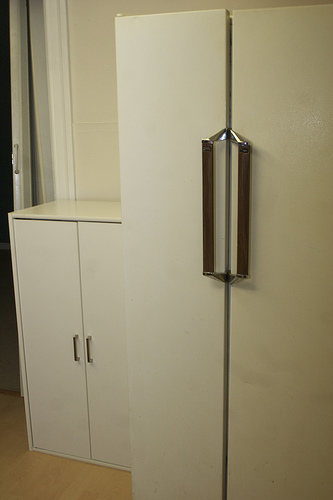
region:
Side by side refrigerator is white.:
[109, 8, 332, 498]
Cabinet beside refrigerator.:
[6, 194, 134, 474]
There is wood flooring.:
[2, 396, 166, 497]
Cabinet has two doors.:
[8, 198, 183, 476]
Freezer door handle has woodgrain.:
[110, 11, 232, 498]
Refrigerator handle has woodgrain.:
[227, 8, 331, 499]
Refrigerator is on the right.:
[227, 5, 332, 498]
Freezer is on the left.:
[112, 6, 228, 498]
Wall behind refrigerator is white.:
[45, 0, 332, 241]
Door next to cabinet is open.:
[1, 0, 74, 407]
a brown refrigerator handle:
[195, 125, 226, 283]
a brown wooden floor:
[0, 392, 135, 499]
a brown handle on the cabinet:
[83, 333, 96, 364]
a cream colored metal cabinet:
[6, 193, 132, 475]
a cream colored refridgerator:
[104, 3, 331, 498]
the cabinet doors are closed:
[8, 194, 133, 476]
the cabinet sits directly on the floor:
[6, 195, 138, 473]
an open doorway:
[3, 2, 74, 399]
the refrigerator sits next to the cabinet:
[110, 5, 325, 484]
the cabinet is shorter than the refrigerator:
[7, 197, 136, 474]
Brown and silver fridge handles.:
[200, 123, 252, 283]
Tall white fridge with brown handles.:
[116, 5, 332, 499]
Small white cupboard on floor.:
[3, 196, 129, 474]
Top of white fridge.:
[119, 4, 330, 21]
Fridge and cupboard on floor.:
[0, 43, 325, 493]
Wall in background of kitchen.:
[70, 12, 117, 208]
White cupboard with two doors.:
[19, 219, 129, 491]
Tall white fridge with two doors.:
[129, 11, 332, 493]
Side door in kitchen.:
[9, 5, 58, 214]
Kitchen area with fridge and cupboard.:
[16, 20, 331, 490]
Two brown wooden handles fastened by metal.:
[201, 128, 249, 284]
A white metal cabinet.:
[112, 2, 331, 498]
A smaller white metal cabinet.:
[7, 199, 130, 489]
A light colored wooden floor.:
[14, 462, 91, 494]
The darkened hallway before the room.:
[0, 305, 14, 396]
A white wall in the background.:
[78, 96, 115, 145]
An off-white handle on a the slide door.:
[8, 139, 26, 177]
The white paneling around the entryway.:
[34, 15, 73, 193]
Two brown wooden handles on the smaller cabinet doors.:
[71, 333, 94, 361]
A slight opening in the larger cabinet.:
[223, 9, 233, 131]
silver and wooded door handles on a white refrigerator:
[198, 114, 261, 303]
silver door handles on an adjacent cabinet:
[63, 328, 102, 368]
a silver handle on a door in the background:
[6, 140, 26, 180]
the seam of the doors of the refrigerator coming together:
[218, 295, 234, 426]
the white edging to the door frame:
[40, 17, 80, 187]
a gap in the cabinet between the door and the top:
[11, 212, 78, 230]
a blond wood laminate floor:
[3, 464, 90, 494]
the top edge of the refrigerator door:
[113, 9, 126, 22]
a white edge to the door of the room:
[3, 25, 28, 123]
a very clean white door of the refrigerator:
[118, 28, 196, 354]